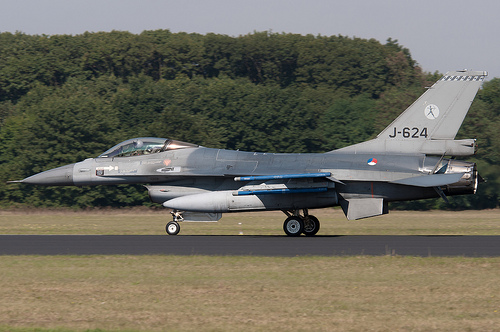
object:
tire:
[283, 213, 306, 238]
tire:
[304, 213, 322, 236]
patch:
[326, 237, 350, 250]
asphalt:
[0, 235, 500, 255]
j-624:
[389, 127, 428, 139]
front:
[6, 157, 93, 185]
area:
[1, 254, 500, 331]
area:
[0, 206, 500, 236]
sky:
[1, 0, 484, 72]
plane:
[0, 63, 500, 281]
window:
[97, 137, 198, 158]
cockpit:
[95, 137, 206, 163]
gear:
[165, 221, 180, 235]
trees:
[0, 29, 500, 211]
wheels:
[283, 215, 320, 235]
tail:
[373, 67, 484, 141]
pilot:
[133, 139, 143, 148]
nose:
[6, 163, 75, 186]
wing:
[232, 172, 335, 196]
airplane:
[7, 68, 488, 235]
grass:
[43, 267, 343, 323]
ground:
[0, 208, 500, 332]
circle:
[367, 158, 378, 166]